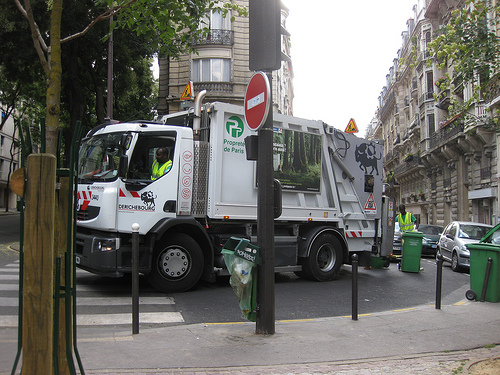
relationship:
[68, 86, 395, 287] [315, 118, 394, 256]
truck has receptacle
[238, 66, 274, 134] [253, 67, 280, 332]
sign on post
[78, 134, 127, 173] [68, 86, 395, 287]
window on truck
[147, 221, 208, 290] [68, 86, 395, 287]
wheel of truck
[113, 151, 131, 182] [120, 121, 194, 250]
mirror on side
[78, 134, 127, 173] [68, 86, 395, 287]
windshield of truck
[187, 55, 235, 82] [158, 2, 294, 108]
window of building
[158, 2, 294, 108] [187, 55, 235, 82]
building has windows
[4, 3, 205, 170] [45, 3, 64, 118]
tree has moss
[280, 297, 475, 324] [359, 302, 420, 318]
curb has yellow lines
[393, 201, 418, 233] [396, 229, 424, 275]
man with trash can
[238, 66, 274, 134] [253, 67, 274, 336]
stop sign on post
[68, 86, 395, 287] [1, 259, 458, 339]
garbage truck on street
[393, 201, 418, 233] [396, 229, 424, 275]
garbageman collecting garbage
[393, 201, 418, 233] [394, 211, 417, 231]
garbageman wears yellow vest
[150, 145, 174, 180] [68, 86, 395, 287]
man driving garbage truck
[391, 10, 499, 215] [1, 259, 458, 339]
building by street